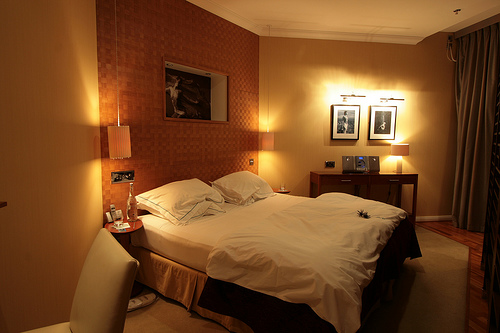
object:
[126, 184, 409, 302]
mattress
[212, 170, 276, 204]
pillow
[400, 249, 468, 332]
floor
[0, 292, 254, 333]
ground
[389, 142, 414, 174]
light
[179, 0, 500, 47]
ceiling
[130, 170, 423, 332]
bed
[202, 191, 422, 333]
blanket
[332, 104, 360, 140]
picture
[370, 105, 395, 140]
picture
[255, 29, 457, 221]
wall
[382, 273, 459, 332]
carpet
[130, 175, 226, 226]
pillow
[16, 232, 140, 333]
chair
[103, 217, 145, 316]
table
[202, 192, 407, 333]
sheet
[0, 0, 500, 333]
bedroom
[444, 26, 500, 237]
curtains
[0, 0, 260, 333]
wall